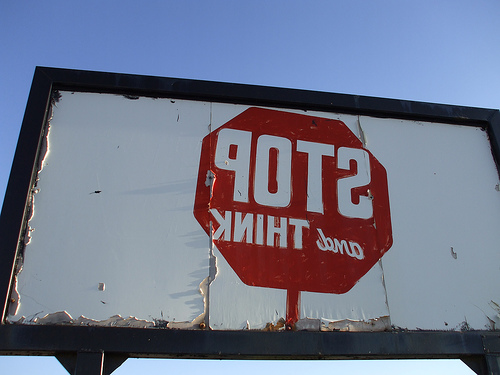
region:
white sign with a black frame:
[7, 56, 497, 363]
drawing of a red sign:
[191, 100, 394, 310]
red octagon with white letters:
[180, 88, 428, 332]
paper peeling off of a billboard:
[24, 125, 229, 345]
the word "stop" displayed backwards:
[215, 123, 387, 213]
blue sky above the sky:
[4, 2, 499, 85]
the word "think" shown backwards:
[200, 204, 306, 263]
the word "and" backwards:
[307, 219, 369, 266]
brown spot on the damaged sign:
[250, 306, 293, 343]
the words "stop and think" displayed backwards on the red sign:
[197, 119, 403, 296]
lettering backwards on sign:
[110, 73, 406, 298]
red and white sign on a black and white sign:
[175, 102, 400, 312]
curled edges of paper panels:
[191, 220, 226, 322]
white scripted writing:
[307, 220, 368, 272]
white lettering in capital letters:
[201, 130, 388, 220]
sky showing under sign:
[135, 351, 407, 368]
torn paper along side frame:
[0, 75, 65, 310]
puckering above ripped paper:
[251, 297, 376, 327]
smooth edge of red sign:
[375, 150, 405, 255]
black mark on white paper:
[71, 176, 111, 201]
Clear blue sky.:
[2, 3, 497, 138]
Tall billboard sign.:
[0, 66, 495, 337]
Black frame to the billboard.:
[1, 51, 487, 361]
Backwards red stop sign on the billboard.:
[177, 81, 407, 331]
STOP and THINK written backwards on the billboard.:
[160, 100, 430, 330]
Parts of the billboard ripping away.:
[15, 276, 416, 331]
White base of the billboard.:
[5, 120, 480, 317]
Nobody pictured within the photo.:
[0, 15, 492, 361]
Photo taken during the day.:
[5, 10, 491, 367]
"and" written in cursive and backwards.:
[316, 224, 369, 268]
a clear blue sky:
[120, 3, 399, 69]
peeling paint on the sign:
[60, 303, 202, 329]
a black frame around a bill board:
[41, 66, 412, 100]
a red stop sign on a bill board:
[187, 106, 404, 311]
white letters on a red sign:
[199, 126, 374, 198]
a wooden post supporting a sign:
[60, 354, 115, 371]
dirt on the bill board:
[91, 176, 108, 211]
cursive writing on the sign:
[318, 221, 371, 267]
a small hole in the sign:
[194, 168, 224, 191]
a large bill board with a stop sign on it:
[6, 56, 498, 371]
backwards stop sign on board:
[189, 97, 417, 304]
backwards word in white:
[207, 120, 397, 228]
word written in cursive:
[305, 221, 373, 264]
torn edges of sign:
[36, 299, 184, 341]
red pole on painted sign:
[277, 285, 312, 324]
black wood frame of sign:
[25, 55, 159, 107]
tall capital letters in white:
[202, 204, 315, 256]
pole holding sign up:
[69, 343, 111, 373]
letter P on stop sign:
[209, 123, 254, 208]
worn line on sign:
[190, 210, 217, 324]